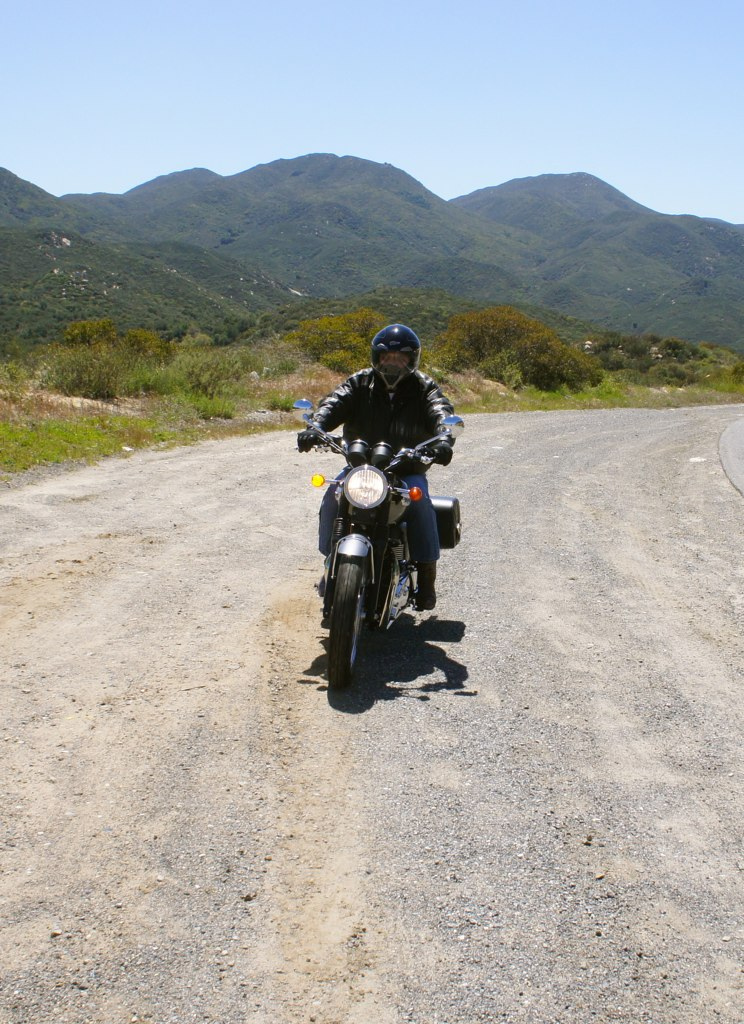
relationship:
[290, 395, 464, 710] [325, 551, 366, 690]
motorcycle has front wheel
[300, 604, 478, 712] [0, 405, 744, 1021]
shadow on ground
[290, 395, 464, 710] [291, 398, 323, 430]
motorcycle has mirror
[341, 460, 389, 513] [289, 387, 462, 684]
headlight on motorcycle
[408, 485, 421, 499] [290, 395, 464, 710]
light on motorcycle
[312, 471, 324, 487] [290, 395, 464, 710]
light on motorcycle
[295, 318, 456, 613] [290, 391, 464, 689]
cyclist riding bike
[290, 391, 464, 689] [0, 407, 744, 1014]
bike on road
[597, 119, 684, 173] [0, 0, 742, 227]
clouds in sky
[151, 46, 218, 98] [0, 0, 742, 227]
clouds in sky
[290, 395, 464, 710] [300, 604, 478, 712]
motorcycle casting shadow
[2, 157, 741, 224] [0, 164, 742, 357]
haze near mountains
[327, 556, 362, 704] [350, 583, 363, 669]
tire on wheel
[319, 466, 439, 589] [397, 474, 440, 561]
legs have jeans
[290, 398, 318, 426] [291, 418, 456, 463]
mirror on handlebars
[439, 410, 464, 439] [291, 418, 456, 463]
mirror on handlebars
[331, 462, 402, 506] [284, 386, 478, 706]
headlight of motorcycle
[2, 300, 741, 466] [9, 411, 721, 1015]
bushes on left side of road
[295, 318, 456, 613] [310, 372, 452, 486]
cyclist wearing jacket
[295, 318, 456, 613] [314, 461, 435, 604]
cyclist wearing jeans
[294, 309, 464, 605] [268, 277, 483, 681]
cyclist on motorcycle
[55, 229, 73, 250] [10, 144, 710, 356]
rock in mountain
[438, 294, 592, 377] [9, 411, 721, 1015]
bush on side of road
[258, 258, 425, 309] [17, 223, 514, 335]
valley between mountains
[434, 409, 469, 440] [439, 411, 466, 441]
surface of a mirror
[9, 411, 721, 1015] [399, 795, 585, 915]
road covered with gravel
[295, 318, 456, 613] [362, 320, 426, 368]
cyclist wearing a helmet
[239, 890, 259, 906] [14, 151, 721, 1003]
rock on ground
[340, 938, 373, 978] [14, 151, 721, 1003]
rock on ground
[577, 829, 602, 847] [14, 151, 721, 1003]
rock on ground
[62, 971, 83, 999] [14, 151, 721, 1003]
rock on ground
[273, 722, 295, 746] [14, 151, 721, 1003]
rock on ground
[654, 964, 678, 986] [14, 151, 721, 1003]
rock on ground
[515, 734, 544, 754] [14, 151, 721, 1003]
rock on ground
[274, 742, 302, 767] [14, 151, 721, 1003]
rock on ground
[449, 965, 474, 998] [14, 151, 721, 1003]
rock on ground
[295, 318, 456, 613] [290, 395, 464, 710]
cyclist on a motorcycle